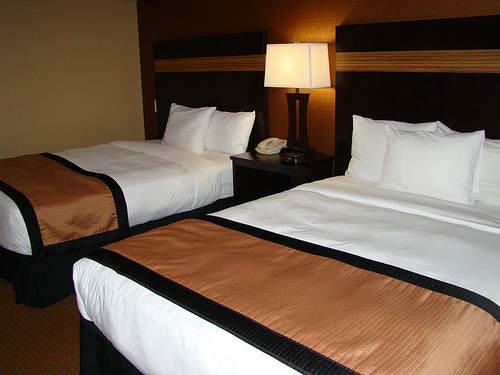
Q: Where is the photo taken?
A: Hotel room.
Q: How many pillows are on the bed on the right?
A: Three.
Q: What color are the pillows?
A: White.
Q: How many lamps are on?
A: One.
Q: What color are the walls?
A: Yellow.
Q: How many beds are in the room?
A: Two.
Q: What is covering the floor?
A: Carpet.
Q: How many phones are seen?
A: One.